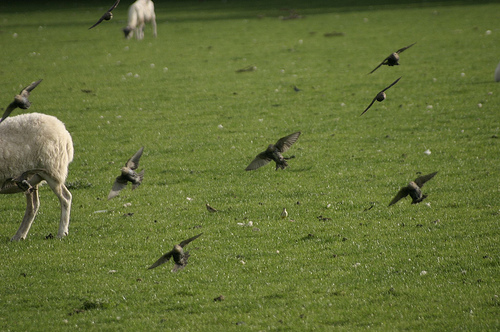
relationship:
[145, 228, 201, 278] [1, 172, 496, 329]
bird close to ground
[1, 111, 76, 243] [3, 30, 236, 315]
sheep in field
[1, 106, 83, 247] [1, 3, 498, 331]
sheep on grass